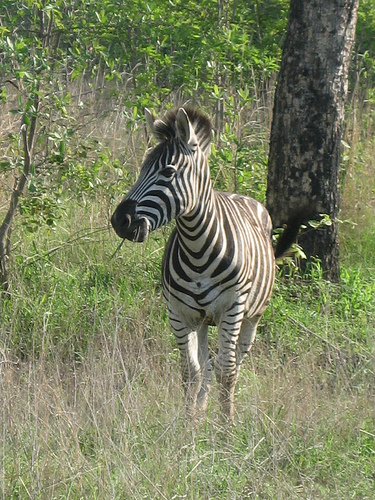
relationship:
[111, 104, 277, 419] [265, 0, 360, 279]
zebra in front of tree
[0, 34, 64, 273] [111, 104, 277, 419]
tree next to zebra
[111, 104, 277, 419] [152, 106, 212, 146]
zebra has hair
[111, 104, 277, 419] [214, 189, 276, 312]
zebra has stripes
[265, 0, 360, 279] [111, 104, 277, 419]
tree behind zebra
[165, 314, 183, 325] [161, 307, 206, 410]
stripe covering leg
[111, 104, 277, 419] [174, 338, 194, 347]
zebra has stripe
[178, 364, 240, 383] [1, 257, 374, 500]
knees covered in grass